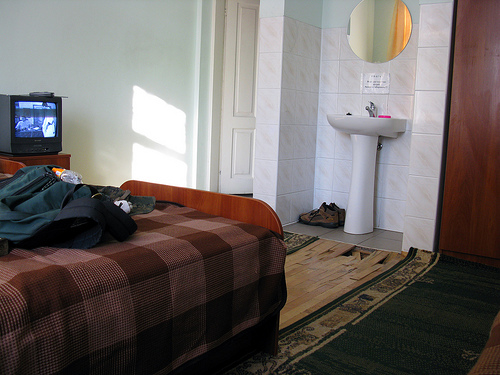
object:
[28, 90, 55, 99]
remote control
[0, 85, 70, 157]
tv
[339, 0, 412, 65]
mirror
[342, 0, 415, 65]
circle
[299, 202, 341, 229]
shoes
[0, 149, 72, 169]
table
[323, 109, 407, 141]
sink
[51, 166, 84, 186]
package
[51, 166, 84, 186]
underwear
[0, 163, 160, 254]
pile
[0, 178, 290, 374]
bed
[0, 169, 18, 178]
foot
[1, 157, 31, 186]
bed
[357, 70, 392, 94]
sign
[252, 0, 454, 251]
wall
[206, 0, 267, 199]
door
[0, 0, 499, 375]
room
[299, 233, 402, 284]
broken area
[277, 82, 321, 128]
tile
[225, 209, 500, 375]
floor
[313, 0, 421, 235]
wall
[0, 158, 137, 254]
backpack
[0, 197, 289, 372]
comforter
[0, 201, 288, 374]
maroon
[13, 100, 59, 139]
screen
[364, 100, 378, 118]
faucet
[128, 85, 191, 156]
light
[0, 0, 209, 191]
wall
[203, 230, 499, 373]
rug